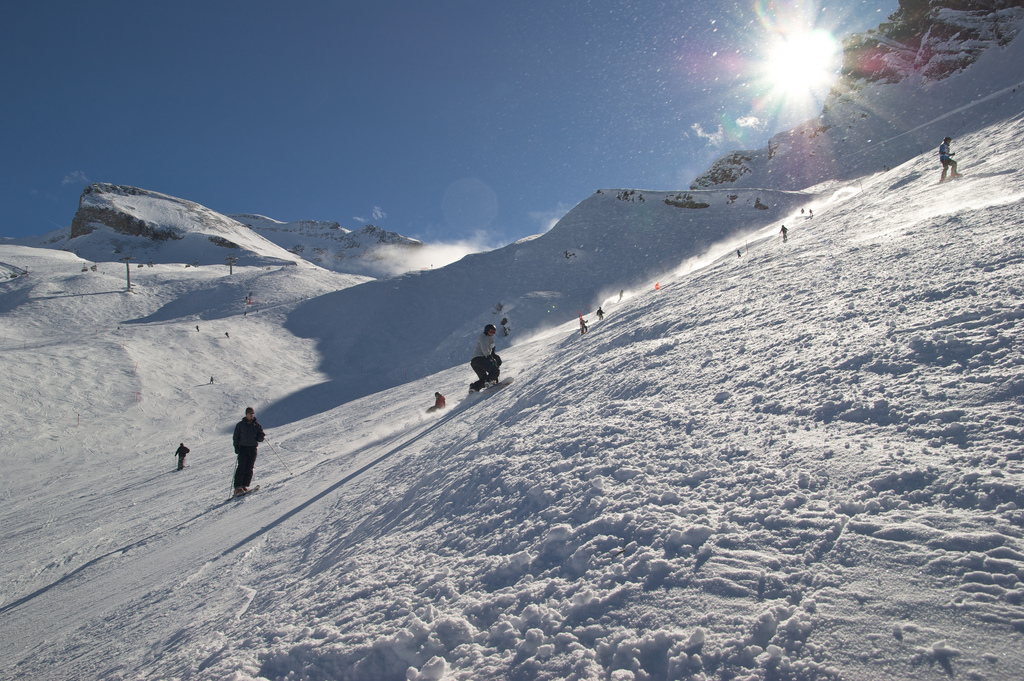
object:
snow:
[553, 518, 627, 621]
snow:
[695, 422, 842, 563]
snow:
[555, 417, 654, 482]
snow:
[846, 321, 967, 402]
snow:
[230, 552, 350, 633]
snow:
[755, 547, 785, 601]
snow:
[755, 555, 857, 601]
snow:
[717, 543, 756, 592]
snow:
[822, 483, 880, 556]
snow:
[855, 578, 957, 624]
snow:
[918, 643, 950, 663]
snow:
[953, 475, 1024, 599]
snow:
[873, 594, 931, 629]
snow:
[811, 624, 869, 644]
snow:
[997, 584, 1013, 660]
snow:
[955, 395, 1010, 471]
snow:
[789, 376, 882, 449]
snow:
[893, 425, 954, 505]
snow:
[807, 471, 925, 528]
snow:
[860, 322, 1002, 358]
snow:
[703, 571, 802, 660]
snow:
[789, 533, 899, 629]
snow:
[929, 552, 1009, 650]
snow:
[588, 549, 697, 644]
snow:
[695, 455, 804, 538]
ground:
[0, 108, 1021, 679]